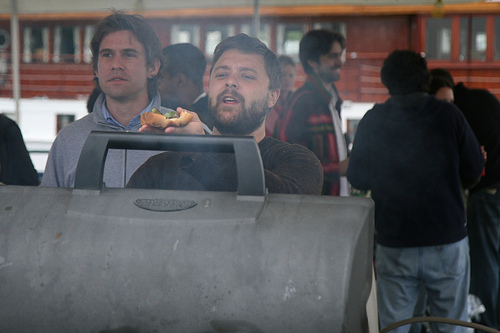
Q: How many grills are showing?
A: One.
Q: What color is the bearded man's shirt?
A: Black.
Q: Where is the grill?
A: In front of men.